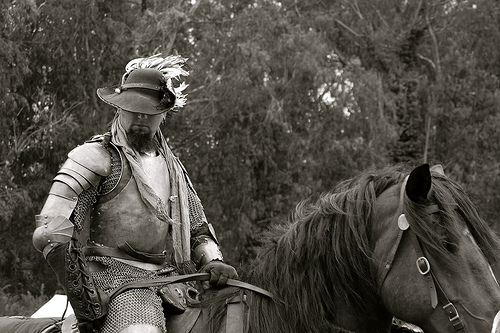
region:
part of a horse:
[352, 175, 397, 232]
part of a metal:
[181, 218, 221, 249]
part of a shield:
[114, 295, 151, 321]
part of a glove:
[210, 264, 238, 303]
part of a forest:
[376, 104, 401, 121]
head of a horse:
[445, 230, 472, 252]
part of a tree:
[226, 130, 258, 149]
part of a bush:
[246, 134, 260, 140]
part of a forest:
[248, 127, 271, 142]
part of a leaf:
[256, 123, 275, 131]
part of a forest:
[401, 88, 413, 100]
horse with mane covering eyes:
[243, 162, 495, 327]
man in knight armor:
[27, 50, 237, 325]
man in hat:
[30, 50, 235, 326]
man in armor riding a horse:
[30, 50, 236, 325]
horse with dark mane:
[241, 156, 493, 327]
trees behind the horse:
[190, 5, 495, 160]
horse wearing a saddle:
[240, 156, 495, 326]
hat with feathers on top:
[95, 46, 185, 111]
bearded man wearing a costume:
[30, 50, 235, 326]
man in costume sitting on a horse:
[30, 51, 238, 328]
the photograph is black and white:
[13, 10, 493, 329]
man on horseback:
[7, 13, 486, 329]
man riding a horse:
[6, 5, 499, 324]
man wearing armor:
[1, 4, 441, 331]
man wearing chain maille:
[3, 3, 498, 328]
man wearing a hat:
[91, 53, 182, 120]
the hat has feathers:
[66, 35, 223, 130]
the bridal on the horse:
[387, 210, 467, 331]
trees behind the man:
[17, 15, 437, 177]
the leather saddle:
[148, 282, 217, 331]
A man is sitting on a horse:
[35, 28, 495, 332]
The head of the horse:
[365, 165, 497, 327]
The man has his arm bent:
[26, 185, 86, 279]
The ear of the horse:
[401, 159, 438, 210]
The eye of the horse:
[436, 228, 462, 262]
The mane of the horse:
[239, 163, 402, 332]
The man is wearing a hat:
[93, 52, 191, 117]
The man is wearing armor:
[33, 133, 225, 272]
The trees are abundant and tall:
[206, 2, 346, 199]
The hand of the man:
[196, 257, 245, 290]